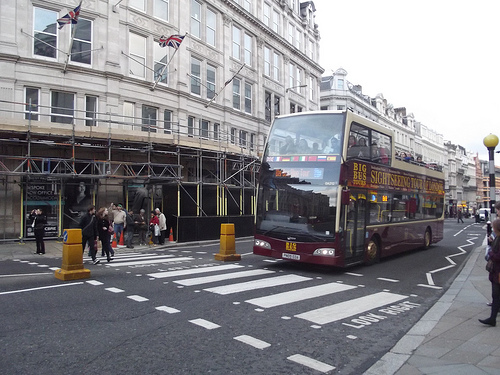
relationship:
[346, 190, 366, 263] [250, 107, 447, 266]
door on bus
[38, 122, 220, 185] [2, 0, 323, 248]
awning on building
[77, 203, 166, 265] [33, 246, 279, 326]
people are crossing street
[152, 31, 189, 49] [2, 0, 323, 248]
flag hanging from building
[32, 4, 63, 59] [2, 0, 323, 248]
window on building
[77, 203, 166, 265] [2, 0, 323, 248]
people standing next to building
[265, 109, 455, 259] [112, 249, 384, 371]
bus on street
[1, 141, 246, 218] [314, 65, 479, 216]
metal on building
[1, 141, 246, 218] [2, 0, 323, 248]
metal on building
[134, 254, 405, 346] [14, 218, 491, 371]
crosswalk on street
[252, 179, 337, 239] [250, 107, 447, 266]
windshield on bus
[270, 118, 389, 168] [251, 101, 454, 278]
people sitting on bus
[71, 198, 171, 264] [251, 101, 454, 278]
people sitting on bus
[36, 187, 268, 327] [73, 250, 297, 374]
dividers in road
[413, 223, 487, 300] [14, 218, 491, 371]
zigzag on street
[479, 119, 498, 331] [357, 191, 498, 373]
lamp post on sidewalk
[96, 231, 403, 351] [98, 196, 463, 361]
lines in road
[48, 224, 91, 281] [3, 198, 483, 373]
pillar in road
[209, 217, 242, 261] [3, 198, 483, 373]
pillar in road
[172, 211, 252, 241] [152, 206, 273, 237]
black walls near subway stairs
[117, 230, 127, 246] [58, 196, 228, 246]
cone on sidewalk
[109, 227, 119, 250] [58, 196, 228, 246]
cone on sidewalk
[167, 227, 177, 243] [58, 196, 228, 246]
cone on sidewalk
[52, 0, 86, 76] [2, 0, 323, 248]
flag mounted to building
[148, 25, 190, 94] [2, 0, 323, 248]
flag mounted to building